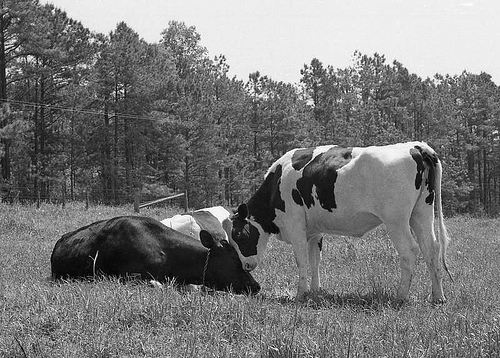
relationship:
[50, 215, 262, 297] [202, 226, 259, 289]
black cow has head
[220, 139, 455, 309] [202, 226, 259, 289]
cow touching head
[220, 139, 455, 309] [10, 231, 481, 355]
cow standing on field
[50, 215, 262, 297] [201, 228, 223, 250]
black cow has ear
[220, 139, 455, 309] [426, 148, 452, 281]
cow has tail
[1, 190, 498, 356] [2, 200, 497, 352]
grass covering ground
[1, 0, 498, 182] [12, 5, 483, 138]
trees in background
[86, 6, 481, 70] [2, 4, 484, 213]
sky in background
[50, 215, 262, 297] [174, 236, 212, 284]
black cow has neck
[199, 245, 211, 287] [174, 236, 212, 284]
rope around neck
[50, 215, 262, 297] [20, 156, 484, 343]
black cow in pasture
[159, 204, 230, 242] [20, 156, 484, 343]
cow in pasture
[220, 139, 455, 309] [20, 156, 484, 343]
cow in pasture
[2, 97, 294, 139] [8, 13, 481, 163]
power lines in background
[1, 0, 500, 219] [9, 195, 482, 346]
trees behind field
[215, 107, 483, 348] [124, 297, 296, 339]
cow standing in grass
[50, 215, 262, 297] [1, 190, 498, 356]
black cow laying in grass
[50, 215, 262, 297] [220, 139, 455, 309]
black cow touching cow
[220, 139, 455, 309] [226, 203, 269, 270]
cow touching head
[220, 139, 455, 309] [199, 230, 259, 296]
cow touching head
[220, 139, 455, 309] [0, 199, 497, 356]
cow in field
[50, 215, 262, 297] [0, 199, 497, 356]
black cow in field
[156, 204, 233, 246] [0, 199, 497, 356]
cow in field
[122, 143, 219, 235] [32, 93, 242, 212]
gate in background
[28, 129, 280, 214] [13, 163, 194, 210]
fence in background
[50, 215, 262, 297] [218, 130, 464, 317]
black cow together with cow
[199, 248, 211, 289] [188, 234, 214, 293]
rope around neck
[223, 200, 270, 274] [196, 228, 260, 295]
head touching head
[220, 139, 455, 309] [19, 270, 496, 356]
cow in grass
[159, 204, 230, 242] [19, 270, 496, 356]
cow in grass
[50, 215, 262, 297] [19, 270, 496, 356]
black cow in grass